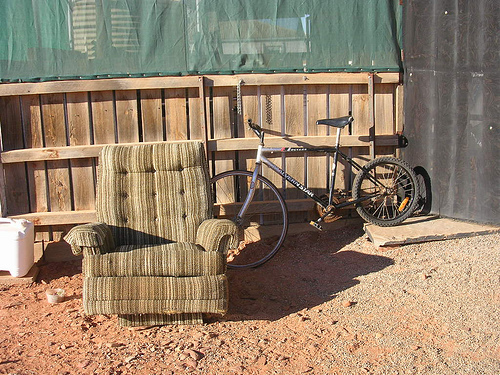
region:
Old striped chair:
[66, 133, 241, 322]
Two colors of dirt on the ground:
[276, 267, 452, 372]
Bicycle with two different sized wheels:
[208, 116, 424, 268]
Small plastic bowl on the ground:
[45, 287, 65, 302]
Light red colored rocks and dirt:
[97, 330, 193, 374]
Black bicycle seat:
[317, 112, 357, 128]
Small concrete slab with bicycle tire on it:
[360, 214, 490, 248]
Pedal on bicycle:
[304, 218, 322, 235]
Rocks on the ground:
[110, 341, 205, 370]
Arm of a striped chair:
[195, 216, 245, 258]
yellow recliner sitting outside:
[82, 143, 236, 332]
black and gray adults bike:
[210, 108, 428, 276]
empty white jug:
[0, 208, 45, 290]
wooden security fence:
[2, 73, 420, 209]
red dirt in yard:
[317, 236, 487, 366]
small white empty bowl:
[40, 283, 74, 310]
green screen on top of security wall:
[8, 3, 447, 84]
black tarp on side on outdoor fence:
[402, 3, 498, 220]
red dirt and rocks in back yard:
[7, 313, 209, 371]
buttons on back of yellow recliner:
[109, 165, 166, 213]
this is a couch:
[77, 146, 203, 337]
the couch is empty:
[85, 150, 210, 320]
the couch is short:
[85, 146, 215, 317]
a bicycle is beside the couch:
[235, 121, 394, 239]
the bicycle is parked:
[247, 112, 392, 249]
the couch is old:
[99, 142, 204, 304]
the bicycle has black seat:
[317, 117, 351, 128]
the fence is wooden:
[50, 75, 248, 135]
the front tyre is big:
[242, 191, 291, 256]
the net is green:
[0, 8, 392, 70]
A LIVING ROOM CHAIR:
[60, 128, 253, 330]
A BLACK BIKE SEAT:
[312, 110, 357, 132]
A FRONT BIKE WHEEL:
[211, 163, 293, 274]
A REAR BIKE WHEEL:
[348, 156, 428, 231]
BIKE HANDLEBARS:
[244, 105, 309, 147]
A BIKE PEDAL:
[300, 208, 330, 238]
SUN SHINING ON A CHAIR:
[60, 128, 277, 334]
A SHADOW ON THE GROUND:
[206, 222, 400, 329]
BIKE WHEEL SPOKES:
[344, 153, 431, 229]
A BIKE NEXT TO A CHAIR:
[59, 101, 454, 327]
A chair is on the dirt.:
[37, 129, 271, 338]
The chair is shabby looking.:
[46, 128, 266, 333]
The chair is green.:
[44, 132, 282, 345]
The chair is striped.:
[54, 131, 270, 336]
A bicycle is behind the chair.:
[199, 103, 429, 277]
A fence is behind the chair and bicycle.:
[0, 60, 433, 286]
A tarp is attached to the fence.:
[0, 0, 423, 86]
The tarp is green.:
[0, 0, 415, 89]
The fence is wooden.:
[0, 60, 421, 226]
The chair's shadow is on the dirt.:
[206, 212, 391, 334]